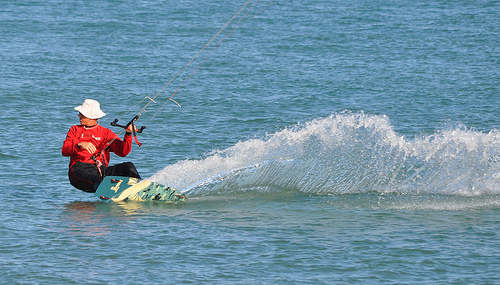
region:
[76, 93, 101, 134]
man is looking backwards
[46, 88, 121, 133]
man wearing a white hat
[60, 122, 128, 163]
man's shirt is red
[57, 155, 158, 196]
man's pants are black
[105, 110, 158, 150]
man is holding handles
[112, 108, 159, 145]
the handles are black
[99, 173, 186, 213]
the surfboard is blue and white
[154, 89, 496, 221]
waves are splashing up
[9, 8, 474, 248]
man is in the water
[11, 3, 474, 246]
body of water is ocean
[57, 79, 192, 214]
the man is kite boarding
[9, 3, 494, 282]
the water is calm with ripples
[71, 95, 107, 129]
the man has a white hat on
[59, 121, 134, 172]
a long sleeve shirt is on the man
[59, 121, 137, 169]
the shirt is red with black trim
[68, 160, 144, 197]
black trousers are on the man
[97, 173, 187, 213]
the kite board is sideways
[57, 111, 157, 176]
the man has a kiteboard harness on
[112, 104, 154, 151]
the man is holding onto the harness with one hand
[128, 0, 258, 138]
the kite is attached to the ropes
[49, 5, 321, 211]
a person is surfing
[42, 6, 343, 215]
a person is wind surfing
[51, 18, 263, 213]
a man is windsurfing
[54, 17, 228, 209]
the man holds the rope in his left hand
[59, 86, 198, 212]
the man is leaning back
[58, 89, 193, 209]
the man is looking back over his right shoulder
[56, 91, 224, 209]
the surfer is wearing red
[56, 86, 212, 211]
the surfer has a white hat on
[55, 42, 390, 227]
the man is pulled on the water while holding the rope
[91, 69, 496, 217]
the surfboard kicks up water behind it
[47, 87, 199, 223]
A man is riding on the water.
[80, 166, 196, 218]
The man rides a board.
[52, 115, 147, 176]
The man's top is red.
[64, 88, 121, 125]
The man wears a hat.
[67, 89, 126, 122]
The hat is white.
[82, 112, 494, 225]
The board creates a spray of water.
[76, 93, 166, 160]
The man holds a handle.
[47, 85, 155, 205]
The man is looking to the left.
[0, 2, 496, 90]
The water is blue.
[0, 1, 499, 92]
The water is calm.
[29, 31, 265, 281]
a man parasailing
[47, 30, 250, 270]
a man parasailing in the water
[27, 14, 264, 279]
a man holding onto a parasail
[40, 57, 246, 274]
a man onto a bar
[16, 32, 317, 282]
a man holding a rope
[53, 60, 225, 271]
a man standing on board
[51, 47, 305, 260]
a man wearing a white hat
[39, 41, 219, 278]
a man wearing a red shirt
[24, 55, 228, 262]
a man wearing a wetsuit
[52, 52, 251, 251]
a man wearing black pants